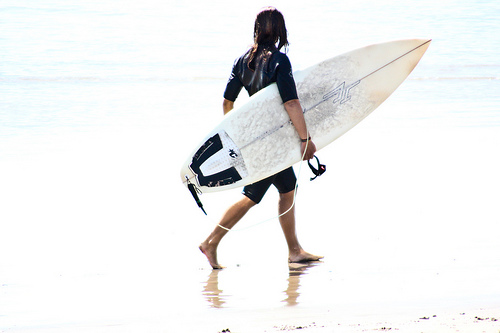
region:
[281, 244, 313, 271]
part of a foot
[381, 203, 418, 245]
part of a shore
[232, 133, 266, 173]
part of a zline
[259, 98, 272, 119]
part oof a board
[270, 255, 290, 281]
part of a shade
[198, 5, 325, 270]
A guy in a wet suit.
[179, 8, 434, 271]
A guy with a surfboard.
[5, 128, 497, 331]
Sand on a beach.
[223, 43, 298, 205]
A black wet suit.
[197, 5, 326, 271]
A guy with long hair.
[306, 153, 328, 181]
Sunglasses in a man's hand.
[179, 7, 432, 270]
A surfer with a board.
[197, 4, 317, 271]
A man walking on the beach.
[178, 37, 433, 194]
A big white surfboard.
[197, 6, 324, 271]
A surfer on the beach.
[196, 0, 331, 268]
this is a lady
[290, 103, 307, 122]
the lady is light skinned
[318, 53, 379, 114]
this is a surfboard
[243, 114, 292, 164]
the surfboard is white in color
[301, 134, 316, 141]
this is a wrist band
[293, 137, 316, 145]
the band is black in color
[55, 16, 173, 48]
this is the sky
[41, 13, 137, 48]
the sky is blue in color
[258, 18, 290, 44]
this is the hair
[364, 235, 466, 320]
this is the beach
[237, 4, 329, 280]
A woman carring a skating board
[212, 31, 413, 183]
A white skating board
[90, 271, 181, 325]
A wet groung surface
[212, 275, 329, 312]
A wet groung surface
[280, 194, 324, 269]
A Bare woman's foot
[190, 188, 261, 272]
A Bare woman's foot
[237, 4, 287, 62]
A black wet hair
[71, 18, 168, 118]
A bight photo background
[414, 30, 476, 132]
A bight photo background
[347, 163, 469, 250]
A bight photo background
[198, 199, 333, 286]
legs of a person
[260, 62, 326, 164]
arm of a person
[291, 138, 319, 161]
hand of a person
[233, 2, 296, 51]
head of a person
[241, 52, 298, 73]
shoulders of a person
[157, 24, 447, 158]
person carrying a surf board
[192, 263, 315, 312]
shadows from the water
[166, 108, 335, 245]
rope connected to surf board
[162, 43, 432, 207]
a white surf board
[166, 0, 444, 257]
person walking on beah